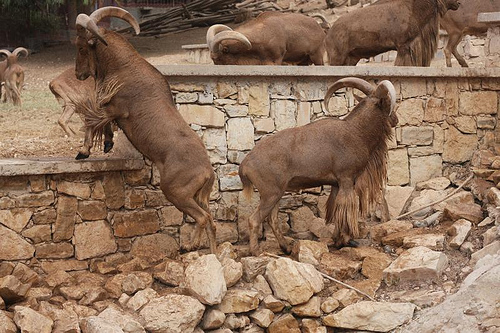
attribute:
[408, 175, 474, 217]
wood — long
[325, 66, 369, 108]
horn — brown, curved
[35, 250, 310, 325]
stones — piled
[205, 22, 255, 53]
horn — long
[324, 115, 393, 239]
hair — long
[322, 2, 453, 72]
ram — large, standing 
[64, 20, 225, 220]
ram — climbing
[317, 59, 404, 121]
horns — long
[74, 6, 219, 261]
goat — brown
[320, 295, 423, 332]
stone — loose, large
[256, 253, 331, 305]
loose stone — large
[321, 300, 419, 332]
stone — loose, large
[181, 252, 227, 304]
stone — large, loose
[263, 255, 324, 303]
stone — large, loose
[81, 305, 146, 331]
stone — large, loose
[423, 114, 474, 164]
wall — light brown, stone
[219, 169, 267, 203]
goat tail — short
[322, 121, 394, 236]
hair — hanging, long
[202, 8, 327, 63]
ram — grazing , large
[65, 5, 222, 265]
mountain goat — long horned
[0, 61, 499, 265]
wall — stone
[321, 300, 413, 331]
rock — large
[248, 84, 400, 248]
ram — walking, large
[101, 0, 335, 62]
panels — stones, stacked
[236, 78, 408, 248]
ram — brown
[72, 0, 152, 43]
horns — long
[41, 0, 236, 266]
goat — climbing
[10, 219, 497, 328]
stone — large, loose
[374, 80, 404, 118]
horn — brown, curved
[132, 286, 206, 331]
rock — large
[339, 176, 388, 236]
hair — longe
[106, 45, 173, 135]
fur — brown